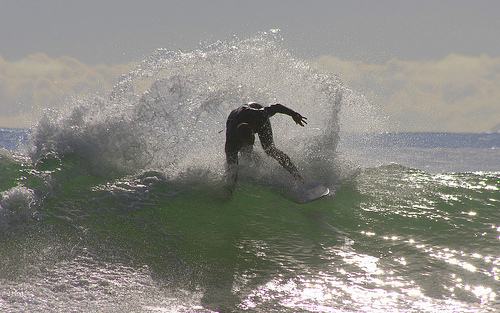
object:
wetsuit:
[223, 102, 307, 183]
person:
[222, 102, 308, 193]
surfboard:
[257, 170, 330, 205]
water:
[0, 27, 500, 313]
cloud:
[393, 54, 500, 132]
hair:
[235, 122, 254, 137]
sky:
[0, 0, 500, 133]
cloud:
[0, 52, 64, 130]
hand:
[223, 178, 237, 194]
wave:
[14, 28, 392, 203]